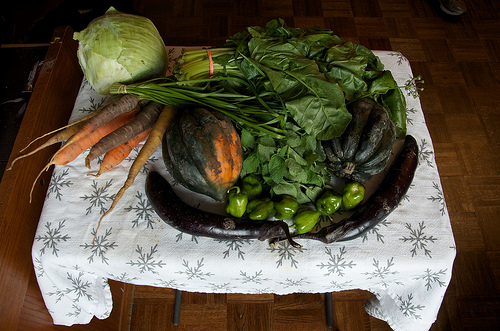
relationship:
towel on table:
[338, 222, 479, 329] [4, 12, 498, 324]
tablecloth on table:
[31, 50, 457, 330] [30, 36, 457, 329]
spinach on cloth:
[208, 70, 368, 231] [11, 184, 233, 275]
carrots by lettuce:
[12, 92, 170, 223] [71, 6, 166, 99]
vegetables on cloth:
[137, 52, 331, 223] [26, 22, 467, 325]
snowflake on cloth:
[126, 238, 166, 276] [26, 22, 467, 325]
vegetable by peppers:
[163, 153, 273, 249] [126, 129, 416, 245]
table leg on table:
[164, 287, 191, 324] [30, 173, 147, 276]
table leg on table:
[322, 290, 337, 327] [30, 173, 147, 276]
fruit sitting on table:
[16, 5, 420, 250] [4, 12, 498, 324]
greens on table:
[206, 19, 402, 224] [37, 17, 149, 329]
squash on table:
[157, 97, 239, 209] [4, 12, 498, 324]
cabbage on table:
[72, 14, 162, 83] [53, 169, 187, 266]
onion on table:
[105, 72, 295, 137] [30, 36, 457, 329]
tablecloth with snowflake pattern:
[31, 50, 457, 330] [40, 222, 158, 272]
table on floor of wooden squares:
[4, 12, 498, 324] [420, 36, 499, 198]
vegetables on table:
[72, 14, 418, 242] [32, 49, 455, 285]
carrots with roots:
[9, 95, 174, 236] [13, 117, 130, 245]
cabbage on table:
[65, 14, 173, 94] [4, 12, 498, 324]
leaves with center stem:
[213, 54, 413, 209] [272, 53, 336, 132]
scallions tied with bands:
[104, 72, 295, 136] [114, 80, 126, 95]